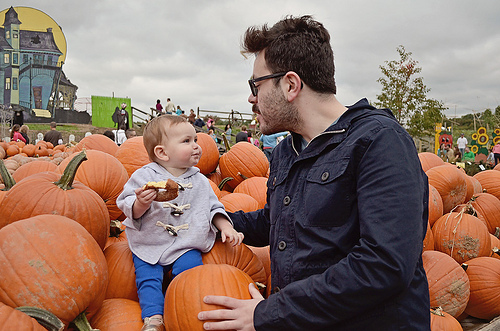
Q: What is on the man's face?
A: Glasses.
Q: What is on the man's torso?
A: A black jacket.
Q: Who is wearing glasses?
A: The man.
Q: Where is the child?
A: On the pumpkins.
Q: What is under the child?
A: Pumpkins.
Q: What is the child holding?
A: A donut.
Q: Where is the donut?
A: In the child's hand.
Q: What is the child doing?
A: Eating.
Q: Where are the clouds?
A: In the sky.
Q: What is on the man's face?
A: Glasses.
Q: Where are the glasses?
A: On the man's face.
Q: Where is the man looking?
A: At the child.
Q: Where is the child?
A: On a pumpkin.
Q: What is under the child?
A: Pumpkins.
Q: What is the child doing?
A: Eating.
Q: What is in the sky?
A: Clouds.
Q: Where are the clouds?
A: In the sky.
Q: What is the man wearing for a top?
A: A black jacket.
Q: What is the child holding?
A: A donut.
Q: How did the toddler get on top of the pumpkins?
A: Man put her there.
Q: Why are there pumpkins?
A: It's nearly Halloween.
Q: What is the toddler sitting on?
A: Pumpkins.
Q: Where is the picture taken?
A: Pumpkin patch.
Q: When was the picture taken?
A: During the fall.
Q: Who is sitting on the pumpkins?
A: Toddler.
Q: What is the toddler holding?
A: Doughnut.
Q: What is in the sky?
A: Clouds.